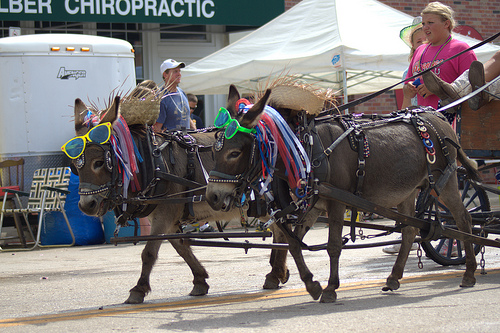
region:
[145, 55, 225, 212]
This is a person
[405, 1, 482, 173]
This is a person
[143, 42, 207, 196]
This is a person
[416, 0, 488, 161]
This is a person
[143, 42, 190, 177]
This is a person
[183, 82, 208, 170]
This is a person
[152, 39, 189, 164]
This is a person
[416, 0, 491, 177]
This is a person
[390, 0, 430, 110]
This is a person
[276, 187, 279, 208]
part of a horse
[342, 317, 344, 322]
edge of a road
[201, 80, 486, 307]
donkey with a large green sunglasses on its head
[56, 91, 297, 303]
donkey wearing yellow glasses on its head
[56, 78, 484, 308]
large oversized glasses on donkeys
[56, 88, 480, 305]
two donkeys walking on a street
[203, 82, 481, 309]
donkey with colorful streams on its head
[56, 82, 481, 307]
two donkeys wearing colorful streams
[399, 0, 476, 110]
blonde hair girl wearing a pink shirt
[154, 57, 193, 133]
man in a blue shirt wearing a white cap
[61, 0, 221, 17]
bold white chiropractic print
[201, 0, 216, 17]
white bold letter C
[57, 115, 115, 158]
yellow glasses on the donkey's head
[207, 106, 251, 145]
green glasses on the donkey's head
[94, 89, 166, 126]
a straw hat on the donkey's head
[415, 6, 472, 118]
a girl wearing a necklace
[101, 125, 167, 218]
chains on the donkey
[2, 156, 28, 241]
a brown wooden chair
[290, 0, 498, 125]
a brick building behind the animals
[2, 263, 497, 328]
two solid yellow lines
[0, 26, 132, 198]
a trailer behind two chairs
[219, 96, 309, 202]
streamers on the donkey's head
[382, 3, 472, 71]
girl in the carriage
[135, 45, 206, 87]
hat on man's head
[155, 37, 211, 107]
man near the animals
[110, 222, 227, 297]
front legs of the animal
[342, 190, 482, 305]
back legs of animal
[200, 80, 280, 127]
ears of the animal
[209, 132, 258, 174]
eye of the animal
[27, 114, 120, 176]
glasses on animal's head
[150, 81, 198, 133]
blue shirt on man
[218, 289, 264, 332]
shadow on the ground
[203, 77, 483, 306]
donkey wearing green sunglasses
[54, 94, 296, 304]
donkey wearing yellow sunglasses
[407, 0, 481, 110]
Woman in pink shirt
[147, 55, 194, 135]
man in blue shirt wearing hat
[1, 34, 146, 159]
White trailer with black logo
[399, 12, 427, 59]
woman wearing a hat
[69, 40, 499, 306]
Two donkeys pulling a cart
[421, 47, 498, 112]
person wearing boots and jeans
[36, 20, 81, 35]
a window on a building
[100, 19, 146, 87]
a window on a building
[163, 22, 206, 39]
a window on a building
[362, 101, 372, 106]
a brick in a wall